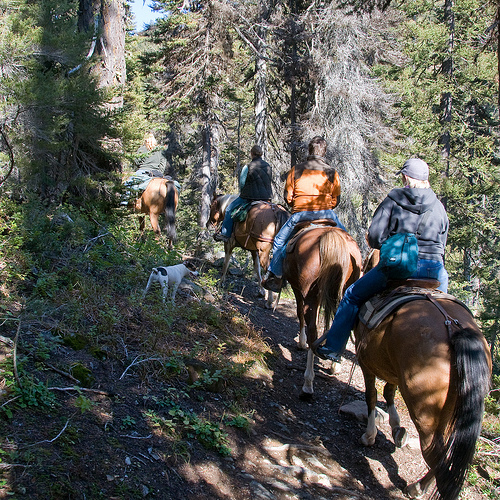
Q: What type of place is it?
A: It is a path.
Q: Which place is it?
A: It is a path.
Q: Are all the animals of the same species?
A: No, there are both horses and dogs.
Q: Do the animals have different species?
A: Yes, they are horses and dogs.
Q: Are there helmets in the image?
A: No, there are no helmets.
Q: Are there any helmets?
A: No, there are no helmets.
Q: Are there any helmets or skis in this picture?
A: No, there are no helmets or skis.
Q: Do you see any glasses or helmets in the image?
A: No, there are no helmets or glasses.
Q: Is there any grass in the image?
A: Yes, there is grass.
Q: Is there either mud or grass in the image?
A: Yes, there is grass.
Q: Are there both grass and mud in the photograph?
A: No, there is grass but no mud.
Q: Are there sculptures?
A: No, there are no sculptures.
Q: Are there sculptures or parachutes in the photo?
A: No, there are no sculptures or parachutes.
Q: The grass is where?
A: The grass is on the ground.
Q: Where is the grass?
A: The grass is on the ground.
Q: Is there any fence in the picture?
A: No, there are no fences.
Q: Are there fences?
A: No, there are no fences.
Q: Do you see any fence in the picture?
A: No, there are no fences.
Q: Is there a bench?
A: No, there are no benches.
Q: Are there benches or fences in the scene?
A: No, there are no benches or fences.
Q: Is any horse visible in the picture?
A: Yes, there are horses.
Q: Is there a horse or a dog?
A: Yes, there are horses.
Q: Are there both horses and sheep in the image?
A: No, there are horses but no sheep.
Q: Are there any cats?
A: No, there are no cats.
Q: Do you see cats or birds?
A: No, there are no cats or birds.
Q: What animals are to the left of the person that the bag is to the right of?
A: The animals are horses.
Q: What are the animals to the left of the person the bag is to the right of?
A: The animals are horses.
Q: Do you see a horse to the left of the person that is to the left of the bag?
A: Yes, there are horses to the left of the person.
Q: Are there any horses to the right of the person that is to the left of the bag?
A: No, the horses are to the left of the person.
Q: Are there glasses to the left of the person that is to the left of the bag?
A: No, there are horses to the left of the person.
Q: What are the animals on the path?
A: The animals are horses.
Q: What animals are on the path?
A: The animals are horses.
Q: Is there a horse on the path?
A: Yes, there are horses on the path.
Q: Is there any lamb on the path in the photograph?
A: No, there are horses on the path.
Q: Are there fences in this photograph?
A: No, there are no fences.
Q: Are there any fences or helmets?
A: No, there are no fences or helmets.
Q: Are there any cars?
A: No, there are no cars.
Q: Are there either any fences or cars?
A: No, there are no cars or fences.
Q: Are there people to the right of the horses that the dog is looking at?
A: Yes, there is a person to the right of the horses.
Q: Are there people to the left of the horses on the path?
A: No, the person is to the right of the horses.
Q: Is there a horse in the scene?
A: Yes, there is a horse.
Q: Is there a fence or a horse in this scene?
A: Yes, there is a horse.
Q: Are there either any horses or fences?
A: Yes, there is a horse.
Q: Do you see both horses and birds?
A: No, there is a horse but no birds.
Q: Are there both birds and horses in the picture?
A: No, there is a horse but no birds.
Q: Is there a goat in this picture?
A: No, there are no goats.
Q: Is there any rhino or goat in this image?
A: No, there are no goats or rhinos.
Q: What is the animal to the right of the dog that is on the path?
A: The animal is a horse.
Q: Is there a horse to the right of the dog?
A: Yes, there is a horse to the right of the dog.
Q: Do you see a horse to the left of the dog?
A: No, the horse is to the right of the dog.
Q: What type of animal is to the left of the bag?
A: The animal is a horse.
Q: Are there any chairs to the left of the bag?
A: No, there is a horse to the left of the bag.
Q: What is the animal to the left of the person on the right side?
A: The animal is a horse.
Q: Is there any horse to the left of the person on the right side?
A: Yes, there is a horse to the left of the person.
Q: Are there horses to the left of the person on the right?
A: Yes, there is a horse to the left of the person.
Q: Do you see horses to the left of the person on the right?
A: Yes, there is a horse to the left of the person.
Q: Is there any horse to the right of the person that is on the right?
A: No, the horse is to the left of the person.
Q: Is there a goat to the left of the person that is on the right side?
A: No, there is a horse to the left of the person.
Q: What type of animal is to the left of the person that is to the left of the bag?
A: The animal is a horse.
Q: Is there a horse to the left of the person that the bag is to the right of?
A: Yes, there is a horse to the left of the person.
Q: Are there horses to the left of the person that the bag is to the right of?
A: Yes, there is a horse to the left of the person.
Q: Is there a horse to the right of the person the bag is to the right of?
A: No, the horse is to the left of the person.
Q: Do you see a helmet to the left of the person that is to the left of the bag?
A: No, there is a horse to the left of the person.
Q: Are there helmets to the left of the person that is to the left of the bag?
A: No, there is a horse to the left of the person.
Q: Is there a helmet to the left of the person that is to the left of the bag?
A: No, there is a horse to the left of the person.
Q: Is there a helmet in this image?
A: No, there are no helmets.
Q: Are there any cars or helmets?
A: No, there are no helmets or cars.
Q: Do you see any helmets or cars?
A: No, there are no helmets or cars.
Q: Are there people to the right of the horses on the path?
A: Yes, there is a person to the right of the horses.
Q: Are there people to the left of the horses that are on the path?
A: No, the person is to the right of the horses.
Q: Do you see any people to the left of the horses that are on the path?
A: No, the person is to the right of the horses.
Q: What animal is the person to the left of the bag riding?
A: The person is riding a horse.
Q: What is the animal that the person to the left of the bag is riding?
A: The animal is a horse.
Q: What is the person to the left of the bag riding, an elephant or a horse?
A: The person is riding a horse.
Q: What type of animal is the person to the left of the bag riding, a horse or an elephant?
A: The person is riding a horse.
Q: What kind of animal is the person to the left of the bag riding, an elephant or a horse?
A: The person is riding a horse.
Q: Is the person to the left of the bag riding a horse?
A: Yes, the person is riding a horse.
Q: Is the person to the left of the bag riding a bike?
A: No, the person is riding a horse.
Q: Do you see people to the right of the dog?
A: Yes, there is a person to the right of the dog.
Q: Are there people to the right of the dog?
A: Yes, there is a person to the right of the dog.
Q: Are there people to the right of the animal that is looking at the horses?
A: Yes, there is a person to the right of the dog.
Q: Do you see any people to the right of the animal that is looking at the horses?
A: Yes, there is a person to the right of the dog.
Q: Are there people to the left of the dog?
A: No, the person is to the right of the dog.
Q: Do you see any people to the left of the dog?
A: No, the person is to the right of the dog.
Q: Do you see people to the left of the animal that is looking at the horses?
A: No, the person is to the right of the dog.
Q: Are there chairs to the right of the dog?
A: No, there is a person to the right of the dog.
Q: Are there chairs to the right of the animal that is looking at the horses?
A: No, there is a person to the right of the dog.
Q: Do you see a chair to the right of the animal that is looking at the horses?
A: No, there is a person to the right of the dog.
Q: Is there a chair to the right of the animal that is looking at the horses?
A: No, there is a person to the right of the dog.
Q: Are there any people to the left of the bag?
A: Yes, there is a person to the left of the bag.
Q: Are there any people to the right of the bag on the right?
A: No, the person is to the left of the bag.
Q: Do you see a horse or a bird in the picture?
A: Yes, there is a horse.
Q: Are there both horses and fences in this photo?
A: No, there is a horse but no fences.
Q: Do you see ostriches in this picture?
A: No, there are no ostriches.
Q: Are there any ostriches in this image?
A: No, there are no ostriches.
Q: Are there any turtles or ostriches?
A: No, there are no ostriches or turtles.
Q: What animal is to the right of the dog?
A: The animal is a horse.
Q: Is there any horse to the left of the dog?
A: No, the horse is to the right of the dog.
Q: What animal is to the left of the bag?
A: The animal is a horse.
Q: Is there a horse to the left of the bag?
A: Yes, there is a horse to the left of the bag.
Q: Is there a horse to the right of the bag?
A: No, the horse is to the left of the bag.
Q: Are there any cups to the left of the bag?
A: No, there is a horse to the left of the bag.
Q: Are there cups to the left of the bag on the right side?
A: No, there is a horse to the left of the bag.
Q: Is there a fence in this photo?
A: No, there are no fences.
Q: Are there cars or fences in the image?
A: No, there are no fences or cars.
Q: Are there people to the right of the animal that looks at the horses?
A: Yes, there is a person to the right of the dog.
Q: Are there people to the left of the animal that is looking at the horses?
A: No, the person is to the right of the dog.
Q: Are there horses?
A: Yes, there is a horse.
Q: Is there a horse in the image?
A: Yes, there is a horse.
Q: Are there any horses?
A: Yes, there is a horse.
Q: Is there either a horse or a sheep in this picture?
A: Yes, there is a horse.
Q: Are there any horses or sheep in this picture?
A: Yes, there is a horse.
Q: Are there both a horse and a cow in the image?
A: No, there is a horse but no cows.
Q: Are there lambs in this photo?
A: No, there are no lambs.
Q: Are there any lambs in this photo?
A: No, there are no lambs.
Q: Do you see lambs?
A: No, there are no lambs.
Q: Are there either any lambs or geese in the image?
A: No, there are no lambs or geese.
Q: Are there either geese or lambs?
A: No, there are no lambs or geese.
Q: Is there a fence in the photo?
A: No, there are no fences.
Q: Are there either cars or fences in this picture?
A: No, there are no fences or cars.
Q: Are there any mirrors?
A: No, there are no mirrors.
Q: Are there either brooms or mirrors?
A: No, there are no mirrors or brooms.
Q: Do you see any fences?
A: No, there are no fences.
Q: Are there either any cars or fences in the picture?
A: No, there are no fences or cars.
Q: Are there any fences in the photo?
A: No, there are no fences.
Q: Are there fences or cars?
A: No, there are no fences or cars.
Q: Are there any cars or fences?
A: No, there are no fences or cars.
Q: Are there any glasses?
A: No, there are no glasses.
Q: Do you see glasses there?
A: No, there are no glasses.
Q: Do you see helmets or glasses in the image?
A: No, there are no glasses or helmets.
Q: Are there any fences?
A: No, there are no fences.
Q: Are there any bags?
A: Yes, there is a bag.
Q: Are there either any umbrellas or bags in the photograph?
A: Yes, there is a bag.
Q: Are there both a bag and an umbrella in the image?
A: No, there is a bag but no umbrellas.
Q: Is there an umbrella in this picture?
A: No, there are no umbrellas.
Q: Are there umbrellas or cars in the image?
A: No, there are no umbrellas or cars.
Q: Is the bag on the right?
A: Yes, the bag is on the right of the image.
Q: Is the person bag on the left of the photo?
A: No, the bag is on the right of the image.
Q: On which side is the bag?
A: The bag is on the right of the image.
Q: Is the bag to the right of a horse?
A: Yes, the bag is to the right of a horse.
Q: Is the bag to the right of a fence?
A: No, the bag is to the right of a horse.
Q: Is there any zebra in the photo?
A: No, there are no zebras.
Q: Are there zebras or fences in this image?
A: No, there are no zebras or fences.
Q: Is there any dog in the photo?
A: Yes, there is a dog.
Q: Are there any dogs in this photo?
A: Yes, there is a dog.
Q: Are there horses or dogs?
A: Yes, there is a dog.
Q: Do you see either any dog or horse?
A: Yes, there is a dog.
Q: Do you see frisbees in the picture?
A: No, there are no frisbees.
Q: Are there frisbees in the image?
A: No, there are no frisbees.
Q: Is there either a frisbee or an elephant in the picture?
A: No, there are no frisbees or elephants.